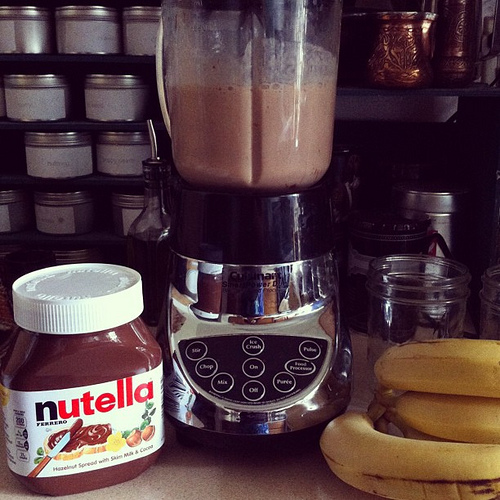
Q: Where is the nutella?
A: To the left of the blender.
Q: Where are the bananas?
A: To the right of the blender.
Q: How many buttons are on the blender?
A: Nine.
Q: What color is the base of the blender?
A: Silver and black.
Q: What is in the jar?
A: Nutella.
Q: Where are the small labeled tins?
A: On the shelf behind the blender.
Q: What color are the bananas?
A: Yellow.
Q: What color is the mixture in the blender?
A: Brown.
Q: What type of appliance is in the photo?
A: A blender.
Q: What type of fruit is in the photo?
A: Bananas.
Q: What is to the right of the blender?
A: Bananas.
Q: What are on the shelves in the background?
A: Silver jars.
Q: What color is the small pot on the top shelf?
A: Copper.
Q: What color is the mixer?
A: Silver.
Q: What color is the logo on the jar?
A: Black and Red.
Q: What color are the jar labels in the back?
A: White.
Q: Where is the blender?
A: On the counter.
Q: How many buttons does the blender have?
A: Nine.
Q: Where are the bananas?
A: To the right of the blender.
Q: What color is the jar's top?
A: White.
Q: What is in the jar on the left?
A: Nutella.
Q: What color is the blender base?
A: Silver and black.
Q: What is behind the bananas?
A: A glass jar.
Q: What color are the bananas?
A: Yellow.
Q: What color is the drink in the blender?
A: Tan.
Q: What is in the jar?
A: Nutella.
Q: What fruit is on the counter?
A: Banana.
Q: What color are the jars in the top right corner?
A: Bronze.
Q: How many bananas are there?
A: 4.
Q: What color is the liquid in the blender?
A: Brown.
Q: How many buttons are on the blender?
A: 9.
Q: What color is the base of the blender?
A: Chrome.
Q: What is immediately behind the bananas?
A: Jar.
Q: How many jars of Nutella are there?
A: 1.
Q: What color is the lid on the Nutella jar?
A: White.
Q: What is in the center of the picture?
A: A blender with a smoothie in it.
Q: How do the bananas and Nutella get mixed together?
A: Inside the blender.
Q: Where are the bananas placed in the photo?
A: On the right.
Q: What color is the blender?
A: It is silver and black.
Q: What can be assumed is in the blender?
A: Bananas and Nutella.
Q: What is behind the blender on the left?
A: Jars.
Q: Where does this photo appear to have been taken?
A: In a kitchen.